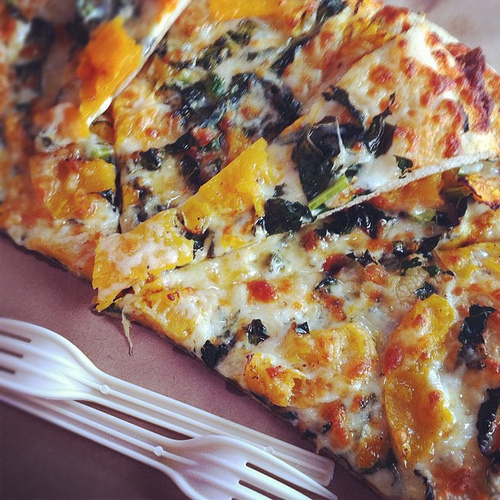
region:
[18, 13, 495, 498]
a delicious piece of pizza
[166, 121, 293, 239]
peppers on the pizza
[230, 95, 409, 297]
pieces of spinich on the pizza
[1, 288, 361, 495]
two plastic forks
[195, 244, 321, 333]
lots of gooey cheese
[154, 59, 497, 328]
a nutritious lunch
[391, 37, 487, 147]
the pizza is browned in areas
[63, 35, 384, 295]
the pizza has some tomatoes on it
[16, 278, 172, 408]
the table is pinkish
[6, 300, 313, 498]
the plastic forks are white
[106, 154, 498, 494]
a cheesy slice of pizza.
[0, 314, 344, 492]
a white plastic fork.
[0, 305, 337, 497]
eating utensils.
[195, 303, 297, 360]
dark toppings on a pizza.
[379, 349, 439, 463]
cheese on a pizza.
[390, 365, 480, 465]
white cheese over a pizza.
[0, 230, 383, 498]
a table with pizza on it.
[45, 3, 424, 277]
a slice of cheesey topping covered pizza.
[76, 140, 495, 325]
a cut in a pizza.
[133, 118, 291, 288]
bell pepper on a pizza.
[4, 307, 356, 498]
white plastic dinner forks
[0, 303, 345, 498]
two white plastic forks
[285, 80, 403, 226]
green spinach pizza topping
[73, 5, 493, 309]
slice of spinach pizza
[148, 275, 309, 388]
mozzarella cheese pizza topping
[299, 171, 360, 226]
piece of green onion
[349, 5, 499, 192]
thin rolled pizza crust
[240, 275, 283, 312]
tomato sauce pizza topping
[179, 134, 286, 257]
cooked peach pizza topping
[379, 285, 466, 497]
slice of peach on pizza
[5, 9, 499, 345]
a flat bread pizza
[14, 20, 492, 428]
flat bread pizza with cheese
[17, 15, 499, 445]
a flat bread sliced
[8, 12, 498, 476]
two plastic forks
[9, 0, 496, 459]
a flat bread pizza cooked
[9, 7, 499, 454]
a cooked flat bread pizza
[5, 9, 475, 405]
a pizza with melted cheese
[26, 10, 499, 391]
a flat bread pizza with melted cheese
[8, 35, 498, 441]
melted chees on flatbread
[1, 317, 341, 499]
White plastic forks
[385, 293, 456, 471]
Peppers on the pizza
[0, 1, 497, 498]
Slices of pizza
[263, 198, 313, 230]
Piece of spinach on the pizza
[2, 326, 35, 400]
Plastic fork prongs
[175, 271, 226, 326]
Mozzarella cheese on pizza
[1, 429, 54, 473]
Gray table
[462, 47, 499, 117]
Burnt piece of pizza crust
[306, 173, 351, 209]
Piece of spinach stalk on pizza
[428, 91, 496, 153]
Pizza crust of cheese pizza